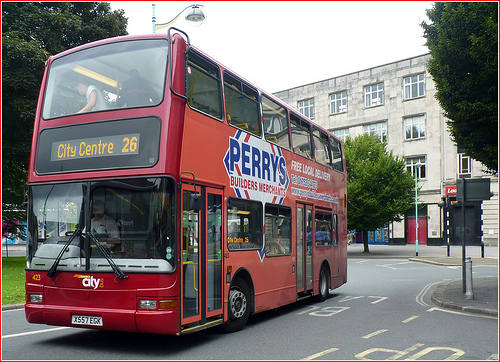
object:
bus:
[14, 26, 349, 345]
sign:
[56, 135, 139, 160]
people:
[71, 78, 107, 113]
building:
[270, 52, 499, 245]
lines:
[362, 329, 389, 341]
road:
[0, 246, 500, 362]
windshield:
[29, 176, 176, 258]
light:
[185, 4, 206, 23]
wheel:
[223, 276, 253, 332]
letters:
[229, 139, 240, 172]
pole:
[461, 179, 468, 297]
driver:
[81, 198, 123, 246]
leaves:
[452, 41, 459, 45]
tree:
[422, 8, 493, 122]